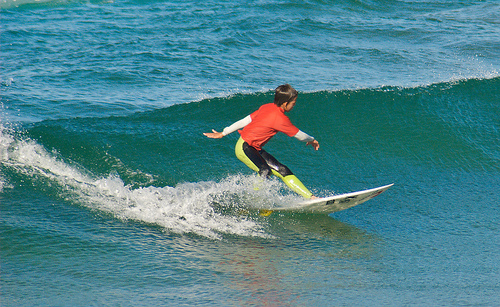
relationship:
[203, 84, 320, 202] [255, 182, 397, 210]
boy on surfboard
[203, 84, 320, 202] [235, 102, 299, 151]
boy wearing shirt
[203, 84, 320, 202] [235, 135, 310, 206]
boy wearing pants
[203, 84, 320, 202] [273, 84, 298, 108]
boy has hair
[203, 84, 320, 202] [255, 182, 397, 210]
boy riding surfboard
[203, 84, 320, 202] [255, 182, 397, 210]
boy turning on surfboard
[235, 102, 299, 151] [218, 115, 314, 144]
shirt has sleeves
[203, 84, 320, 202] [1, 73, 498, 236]
boy on wave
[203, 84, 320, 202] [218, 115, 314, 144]
boy has sleeves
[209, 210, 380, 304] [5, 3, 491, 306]
reflection in water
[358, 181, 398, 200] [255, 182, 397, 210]
tip of surfboard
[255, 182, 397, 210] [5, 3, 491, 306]
surfboard on water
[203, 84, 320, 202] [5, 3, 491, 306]
boy surfing on water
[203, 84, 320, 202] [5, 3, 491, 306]
boy surfing in water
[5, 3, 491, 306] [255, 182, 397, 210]
water splashing from surfboard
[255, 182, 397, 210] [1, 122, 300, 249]
surfboard breaking water